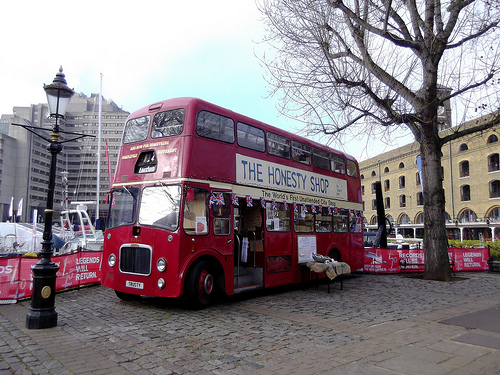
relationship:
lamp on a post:
[44, 85, 73, 118] [14, 123, 97, 330]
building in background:
[359, 108, 499, 243] [3, 2, 499, 239]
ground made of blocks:
[1, 274, 499, 374] [442, 307, 499, 331]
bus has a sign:
[100, 98, 365, 308] [235, 154, 348, 202]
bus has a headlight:
[100, 98, 365, 308] [157, 257, 166, 273]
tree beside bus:
[255, 3, 491, 280] [100, 98, 365, 308]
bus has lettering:
[100, 98, 365, 308] [240, 160, 329, 194]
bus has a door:
[100, 98, 365, 308] [234, 201, 263, 297]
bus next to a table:
[100, 98, 365, 308] [307, 260, 347, 291]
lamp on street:
[43, 85, 76, 118] [4, 271, 499, 375]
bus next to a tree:
[100, 98, 365, 308] [255, 3, 491, 280]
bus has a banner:
[100, 98, 365, 308] [234, 154, 349, 204]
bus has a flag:
[100, 98, 365, 308] [210, 191, 222, 207]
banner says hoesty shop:
[234, 154, 349, 204] [266, 165, 329, 194]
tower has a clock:
[414, 82, 450, 132] [436, 102, 445, 117]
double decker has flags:
[97, 96, 366, 307] [247, 194, 253, 205]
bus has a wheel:
[100, 98, 365, 308] [186, 259, 216, 310]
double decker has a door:
[97, 96, 366, 307] [234, 201, 263, 297]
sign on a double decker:
[235, 154, 348, 202] [97, 96, 366, 307]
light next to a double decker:
[2, 275, 499, 374] [97, 96, 366, 307]